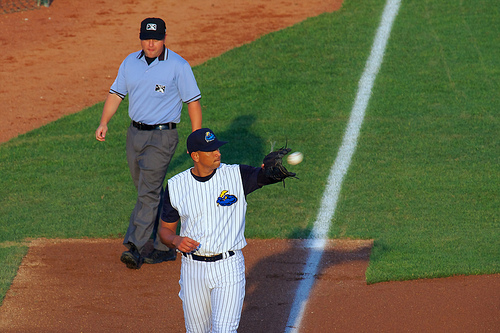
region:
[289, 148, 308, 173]
baseball almost to the mitt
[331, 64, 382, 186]
white chalk line on the field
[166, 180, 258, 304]
player is wearing a pinstriped uniform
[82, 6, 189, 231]
umpire behind the plaer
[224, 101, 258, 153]
shadow of the umpire in the grass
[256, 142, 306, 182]
player's mitt on his hand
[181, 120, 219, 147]
player is wearing a hat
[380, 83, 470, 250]
grass of the outfield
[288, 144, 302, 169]
a white baseball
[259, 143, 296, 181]
a black baseball glove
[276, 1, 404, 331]
a long white line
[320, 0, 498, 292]
a section of green grass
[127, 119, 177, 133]
a man's black belt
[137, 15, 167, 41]
a black and white baseball cap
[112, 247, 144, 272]
a man's black shoe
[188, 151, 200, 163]
the ear of a man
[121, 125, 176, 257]
a man's gray pants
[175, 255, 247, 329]
part of a man's pants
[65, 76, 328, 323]
men playing baseball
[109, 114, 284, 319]
a man in a baseball uniform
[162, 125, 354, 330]
a man wearing a baseball mitt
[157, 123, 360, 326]
a man catching a baseball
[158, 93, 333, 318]
a man on a baseball field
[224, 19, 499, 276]
a baseball field with lines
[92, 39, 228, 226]
a man walking outside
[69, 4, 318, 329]
a major baseball league player and umpire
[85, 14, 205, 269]
a major league baseball umpire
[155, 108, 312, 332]
a major league baseball player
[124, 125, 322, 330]
a player catching the ball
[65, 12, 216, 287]
an umpire walking behind a player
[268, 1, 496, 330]
a major league baseball field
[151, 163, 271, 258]
a baseball jersey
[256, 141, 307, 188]
a glove catching a ball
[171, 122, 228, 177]
the head of a man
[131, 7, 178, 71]
the head of a man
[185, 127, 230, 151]
A blue baseball cap being worn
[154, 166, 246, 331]
A professional baseball uniform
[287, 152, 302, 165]
A baseball about to be caught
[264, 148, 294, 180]
A baseball glove about to catch a ball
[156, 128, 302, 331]
A baseball player practicing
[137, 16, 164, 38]
A blue baseball cap being worn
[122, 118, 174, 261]
Grey mens slacks being worn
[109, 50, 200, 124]
A light blue polo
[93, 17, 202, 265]
A baseball official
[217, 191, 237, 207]
The logo of the players baseball team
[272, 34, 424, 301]
a line on the field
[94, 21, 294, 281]
a man on the field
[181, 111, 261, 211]
a man wearin g ahat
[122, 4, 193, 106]
a man wearing a hat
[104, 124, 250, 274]
a man wearing a jersey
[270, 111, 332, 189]
a ball in the air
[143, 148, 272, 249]
player wearing a white jersey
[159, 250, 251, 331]
player wearing white pants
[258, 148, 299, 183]
player wearing a black glove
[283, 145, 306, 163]
player catching a white ball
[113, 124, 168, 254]
umpire wearing gray pants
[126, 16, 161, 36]
umpire wearing a blue hat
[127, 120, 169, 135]
umpire wearing a black belt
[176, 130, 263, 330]
mixed skin baseball player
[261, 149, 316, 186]
catching baseball in glove